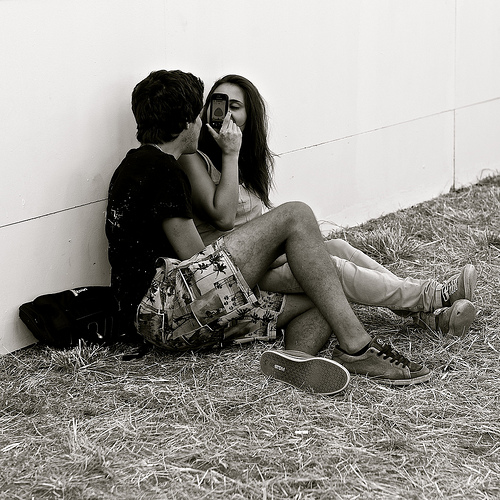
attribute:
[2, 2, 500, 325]
wall — white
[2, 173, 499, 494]
grass — thick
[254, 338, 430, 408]
shoes — brown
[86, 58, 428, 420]
boy — sitting, white, happy, short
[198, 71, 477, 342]
girl — sitting, white, skinny, short, happy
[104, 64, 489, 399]
couple — young